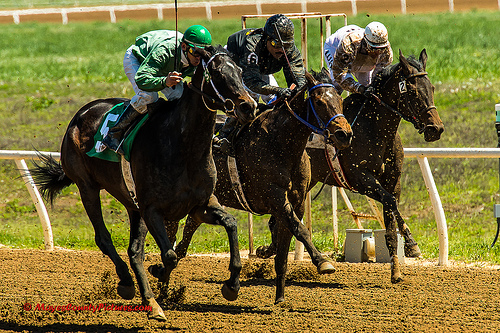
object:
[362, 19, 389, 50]
helmet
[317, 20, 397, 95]
jockey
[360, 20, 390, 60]
head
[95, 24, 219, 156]
man bending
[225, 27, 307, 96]
jacket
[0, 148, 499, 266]
rail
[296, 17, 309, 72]
post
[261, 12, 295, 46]
helmet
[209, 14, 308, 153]
jockey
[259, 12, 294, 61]
head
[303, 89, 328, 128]
horse bridle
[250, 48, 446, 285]
horse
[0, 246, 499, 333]
track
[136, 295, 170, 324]
hooves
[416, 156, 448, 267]
post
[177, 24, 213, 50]
helmet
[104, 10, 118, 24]
post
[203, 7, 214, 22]
post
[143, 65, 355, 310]
horse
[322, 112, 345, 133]
horse bridle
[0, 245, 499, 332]
dirt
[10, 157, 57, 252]
post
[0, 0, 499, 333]
ground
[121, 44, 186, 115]
pants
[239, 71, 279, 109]
pants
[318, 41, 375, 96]
pants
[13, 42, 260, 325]
horse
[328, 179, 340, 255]
metal post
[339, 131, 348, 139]
nostril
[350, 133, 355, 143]
nostril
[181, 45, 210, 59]
glasses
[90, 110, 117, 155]
number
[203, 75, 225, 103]
reins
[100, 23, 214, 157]
jockey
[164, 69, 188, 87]
hands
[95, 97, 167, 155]
saddle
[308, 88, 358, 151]
horse's face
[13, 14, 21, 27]
post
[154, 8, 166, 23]
post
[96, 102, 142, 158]
boots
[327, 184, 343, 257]
post